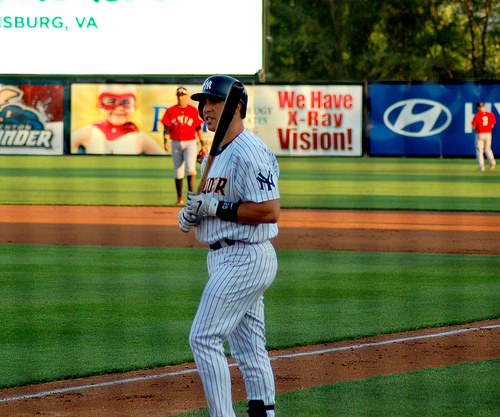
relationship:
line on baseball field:
[0, 324, 499, 404] [1, 154, 499, 416]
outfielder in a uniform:
[471, 102, 496, 173] [472, 110, 496, 165]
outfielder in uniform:
[471, 102, 496, 173] [472, 110, 496, 165]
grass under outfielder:
[1, 156, 499, 211] [471, 102, 496, 173]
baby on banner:
[69, 83, 167, 155] [69, 83, 365, 158]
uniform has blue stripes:
[189, 127, 278, 416] [188, 128, 278, 416]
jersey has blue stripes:
[195, 127, 280, 244] [194, 127, 281, 243]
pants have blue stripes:
[188, 239, 278, 416] [188, 239, 278, 416]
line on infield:
[0, 324, 499, 404] [0, 243, 499, 415]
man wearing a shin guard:
[163, 86, 208, 205] [176, 178, 183, 198]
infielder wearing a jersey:
[163, 86, 208, 205] [163, 104, 204, 141]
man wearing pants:
[163, 86, 208, 205] [171, 139, 197, 180]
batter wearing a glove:
[179, 75, 280, 416] [185, 192, 221, 217]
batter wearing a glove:
[179, 75, 280, 416] [179, 209, 201, 232]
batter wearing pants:
[179, 75, 280, 416] [188, 239, 278, 416]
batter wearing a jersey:
[179, 75, 280, 416] [195, 127, 280, 244]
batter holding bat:
[179, 75, 280, 416] [180, 82, 244, 234]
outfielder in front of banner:
[471, 102, 496, 173] [367, 81, 499, 159]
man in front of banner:
[163, 86, 208, 205] [69, 83, 365, 158]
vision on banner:
[279, 129, 346, 152] [69, 83, 365, 158]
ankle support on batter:
[246, 399, 275, 416] [179, 75, 280, 416]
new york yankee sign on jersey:
[255, 170, 275, 192] [195, 127, 280, 244]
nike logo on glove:
[195, 200, 201, 215] [185, 192, 221, 217]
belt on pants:
[209, 237, 236, 249] [188, 239, 278, 416]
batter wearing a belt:
[179, 75, 280, 416] [209, 237, 236, 249]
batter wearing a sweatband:
[179, 75, 280, 416] [216, 200, 240, 224]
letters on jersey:
[202, 176, 228, 194] [195, 127, 280, 244]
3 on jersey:
[482, 114, 489, 128] [471, 111, 495, 133]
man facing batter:
[163, 86, 208, 205] [179, 75, 280, 416]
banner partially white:
[69, 83, 365, 158] [242, 85, 363, 156]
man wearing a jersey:
[163, 86, 208, 205] [163, 104, 204, 141]